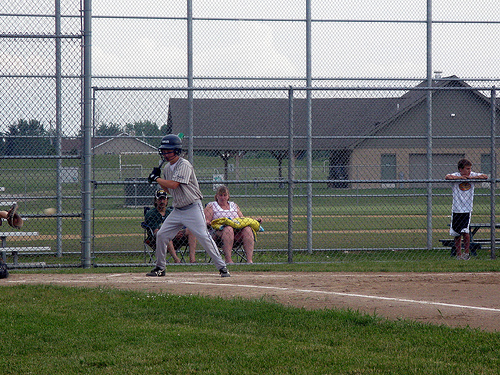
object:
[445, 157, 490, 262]
boy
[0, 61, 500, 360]
baseball game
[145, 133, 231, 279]
player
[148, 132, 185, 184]
bat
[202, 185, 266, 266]
lady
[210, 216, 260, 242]
yellow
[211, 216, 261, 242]
blanket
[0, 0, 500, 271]
fence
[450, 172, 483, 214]
shirt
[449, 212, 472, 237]
shorts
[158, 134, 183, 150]
helmet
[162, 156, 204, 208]
shirt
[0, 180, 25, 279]
person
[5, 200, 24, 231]
catcher's mitt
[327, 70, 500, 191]
building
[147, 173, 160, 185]
hand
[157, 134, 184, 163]
head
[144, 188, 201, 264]
person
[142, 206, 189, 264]
chair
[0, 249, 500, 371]
field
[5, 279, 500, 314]
line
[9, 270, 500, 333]
dirt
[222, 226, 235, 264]
leg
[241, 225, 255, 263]
leg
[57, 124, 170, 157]
building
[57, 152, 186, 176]
hill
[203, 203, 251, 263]
chair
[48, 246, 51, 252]
edge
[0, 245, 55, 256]
bleacher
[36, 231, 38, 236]
edge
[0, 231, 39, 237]
bleacher